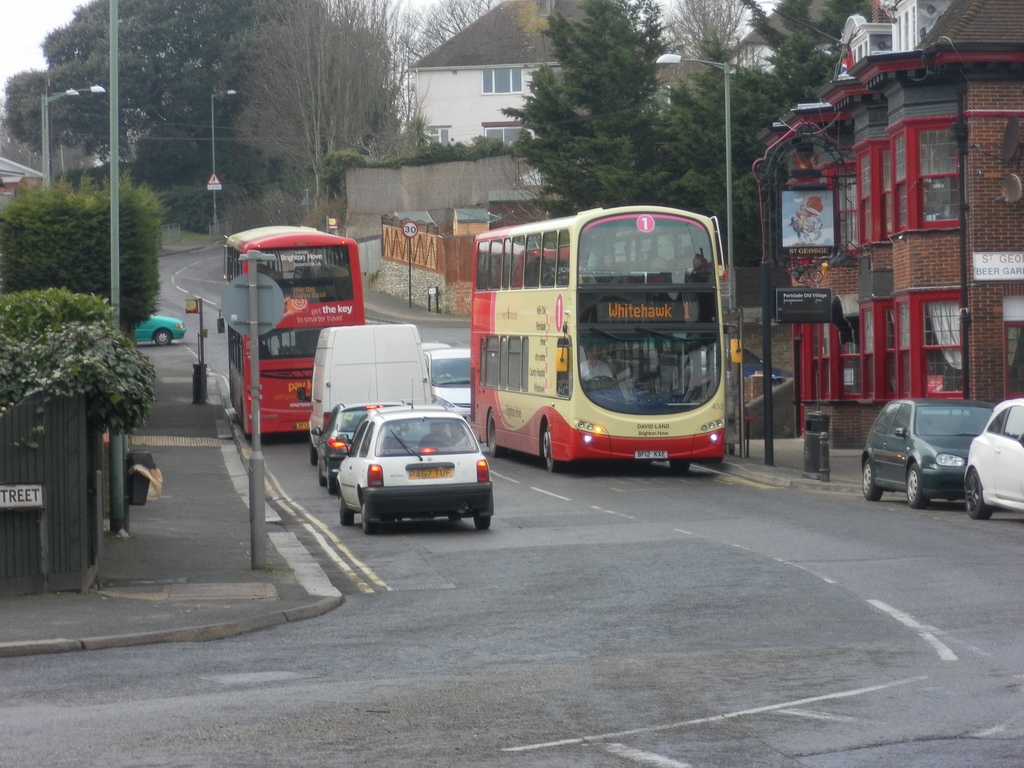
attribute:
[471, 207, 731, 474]
doubledeckerbus — red , yellow 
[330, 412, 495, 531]
dcompactcar — small, white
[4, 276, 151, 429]
greenivy — green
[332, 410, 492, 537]
whitecar — white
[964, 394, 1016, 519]
car — white 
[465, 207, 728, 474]
bus — large , red , tan 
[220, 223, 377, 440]
redbus — large, red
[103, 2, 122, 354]
streetlight — tall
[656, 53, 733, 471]
streetlight — tall 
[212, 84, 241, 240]
streetlight — tall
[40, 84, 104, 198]
streetlight — tall